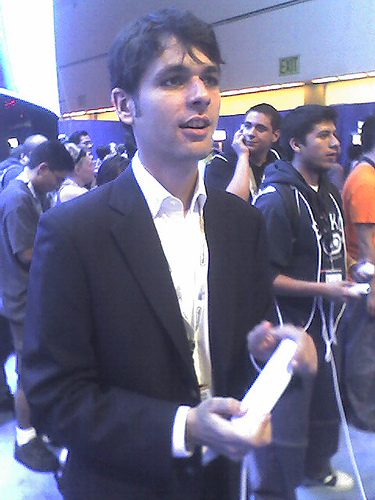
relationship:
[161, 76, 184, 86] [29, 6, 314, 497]
eye of man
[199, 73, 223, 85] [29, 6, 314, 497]
eye of man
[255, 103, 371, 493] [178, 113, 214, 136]
man has mouth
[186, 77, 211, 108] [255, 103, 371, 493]
nose of man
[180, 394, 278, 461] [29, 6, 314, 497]
hand on man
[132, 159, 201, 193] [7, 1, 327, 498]
neck on man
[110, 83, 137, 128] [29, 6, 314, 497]
ear of man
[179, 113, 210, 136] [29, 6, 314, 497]
mouth of man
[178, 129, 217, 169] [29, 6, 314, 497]
chin on man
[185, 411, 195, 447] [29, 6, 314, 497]
wrist of man